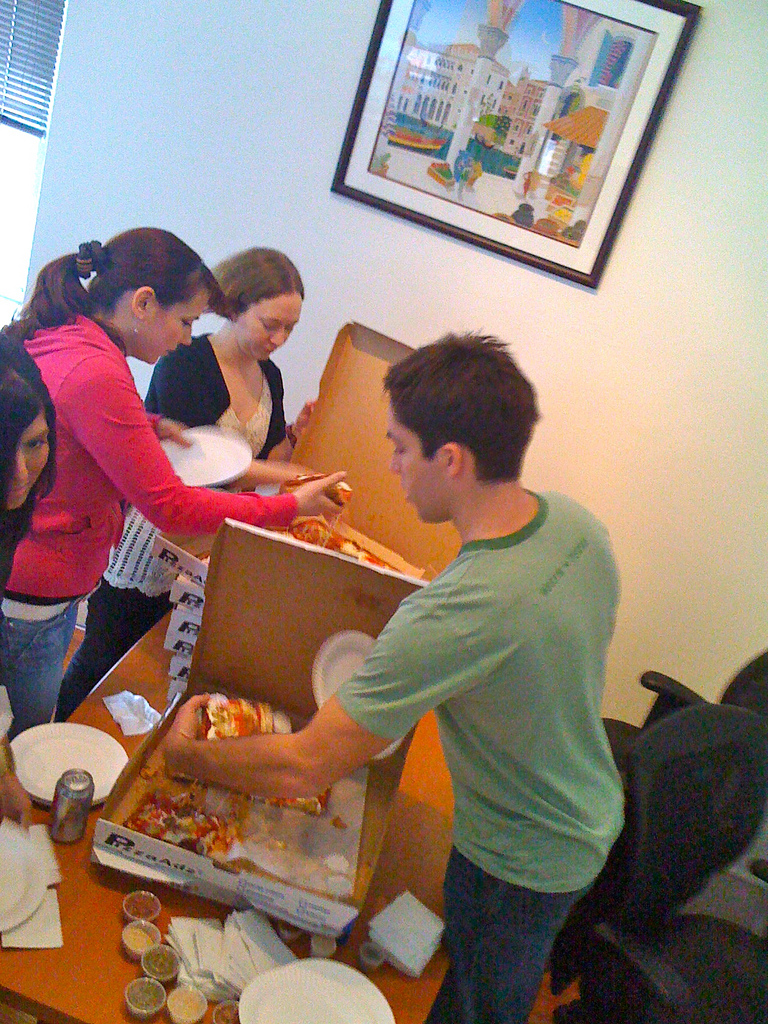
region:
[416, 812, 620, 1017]
Man wearing pants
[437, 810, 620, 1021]
Man is wearing pants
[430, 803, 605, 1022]
Man wearing blue pants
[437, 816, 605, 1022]
Man is wearing blue pants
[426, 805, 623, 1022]
Man wearing blue jeans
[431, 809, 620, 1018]
Man is wearing blue jeans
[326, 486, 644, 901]
Man wearing a green shirt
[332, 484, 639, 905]
Man is wearing a green shirt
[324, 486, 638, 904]
Man wearing a green t-shirt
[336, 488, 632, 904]
Man is wearing a green t-shirt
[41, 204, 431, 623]
Two women picking up pizza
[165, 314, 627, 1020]
Man getting a piece of pizza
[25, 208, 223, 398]
Woman's hair up in ponytail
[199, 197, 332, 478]
Woman holding pizza box open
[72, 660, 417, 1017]
Pizza and toppings on table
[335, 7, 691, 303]
Framed art piece hanging on wall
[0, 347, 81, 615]
Woman with long, dark hair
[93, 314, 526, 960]
Multiple pizza boxes on table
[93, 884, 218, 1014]
The condiment containers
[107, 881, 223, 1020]
A set of condiment containers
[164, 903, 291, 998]
The white napkins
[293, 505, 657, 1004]
The man in a green shirt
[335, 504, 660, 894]
The green shirt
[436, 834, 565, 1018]
The dark jean pant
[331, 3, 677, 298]
A picture on the wall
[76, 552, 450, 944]
The white pizza box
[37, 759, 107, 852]
The silver soda can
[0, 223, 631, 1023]
People getting pizza from take-out boxes on the table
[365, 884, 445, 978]
Paper napkins on the table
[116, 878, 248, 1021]
Containers of various sauces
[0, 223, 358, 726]
Woman picking up a slice of pizza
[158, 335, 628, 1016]
Boy in a green t-shirt getting a slice of pizza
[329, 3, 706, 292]
Picture on the wall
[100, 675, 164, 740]
Crumpled napkin on the table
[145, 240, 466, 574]
Woman holding open a pizza box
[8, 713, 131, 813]
White plate on the table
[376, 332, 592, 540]
the head of a young man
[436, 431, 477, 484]
the ear of a young man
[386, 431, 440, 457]
the eye of a young man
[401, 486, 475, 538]
the chin of a young man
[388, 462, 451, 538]
the mouth of a young man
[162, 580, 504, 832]
the arm of a young man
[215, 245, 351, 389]
the head of a woman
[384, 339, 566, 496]
the hair of a young man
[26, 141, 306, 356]
the hair of a woman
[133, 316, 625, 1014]
man picking up piece of pizza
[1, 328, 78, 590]
woman with long brown hair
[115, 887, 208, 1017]
plastic containers of sauce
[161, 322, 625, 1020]
Brown haired guy in a green shirt.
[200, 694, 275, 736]
Piece of pizza a guy is grabbing.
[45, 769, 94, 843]
Silver unopened can of soda.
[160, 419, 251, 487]
White round plate a girl in pink is holding.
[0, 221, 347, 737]
Girl in a pink sweatshirt and jeans.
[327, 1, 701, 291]
Black framed picture on the wall.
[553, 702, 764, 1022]
Bigger black desk chair.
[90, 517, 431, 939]
Cardboard pizza box a boy in green is digging into.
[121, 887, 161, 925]
Top clear container near a pizza box.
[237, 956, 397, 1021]
Stack of paper plates by green shirt boys pants.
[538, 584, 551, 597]
black letter on shirt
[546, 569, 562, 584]
black letter on shirt